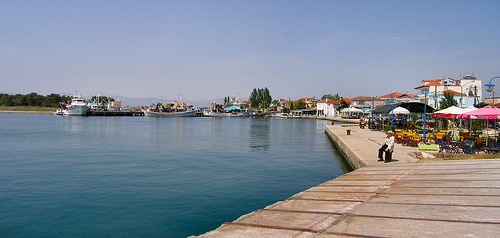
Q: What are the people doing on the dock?
A: They are fishing.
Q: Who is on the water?
A: There are no people on the water.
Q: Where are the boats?
A: Tied too the dock.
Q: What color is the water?
A: Blue.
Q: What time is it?
A: Daytime.